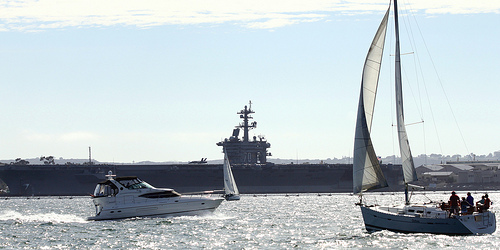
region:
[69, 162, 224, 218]
boat in the ocean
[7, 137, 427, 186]
large battleship in ocean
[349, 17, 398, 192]
sails being blown by wind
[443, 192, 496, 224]
people sitting on boat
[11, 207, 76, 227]
ripples caused by the boat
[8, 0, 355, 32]
clouds in the sky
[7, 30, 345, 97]
clear blue sky during the day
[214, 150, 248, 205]
small sailboat in the ocean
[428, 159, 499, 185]
houses in the background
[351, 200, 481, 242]
blue and white boat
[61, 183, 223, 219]
white boat on water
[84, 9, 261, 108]
blue and white sky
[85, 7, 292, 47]
thin clouds in sky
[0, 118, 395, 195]
large boat in distance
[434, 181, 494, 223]
people on small boat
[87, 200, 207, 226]
black stripe on boat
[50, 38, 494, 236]
boats on the water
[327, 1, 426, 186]
sail of the boat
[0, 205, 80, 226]
wave on the water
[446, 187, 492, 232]
people on the boat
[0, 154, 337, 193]
large boat on water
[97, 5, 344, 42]
the clouds are long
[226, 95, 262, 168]
top of the boat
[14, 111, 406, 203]
a big vessel on the water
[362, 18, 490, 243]
a sailboat on the water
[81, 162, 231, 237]
a motor boat on the water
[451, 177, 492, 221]
a group of people on the sailboat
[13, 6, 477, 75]
white clouds in a blue sky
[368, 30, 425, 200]
the sails of the sailboat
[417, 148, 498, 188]
buildings on the land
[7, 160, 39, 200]
the number seven on the side of the ship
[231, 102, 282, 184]
communication center of the ship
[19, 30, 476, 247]
four boats of different sizes on the water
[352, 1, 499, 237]
a larger sailboat with several people sailing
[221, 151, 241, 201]
a sail boat nearer to the ship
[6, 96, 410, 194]
a large commercial ship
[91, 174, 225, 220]
a large motorboat cruises by the sailboat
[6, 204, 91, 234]
wake left by the motor boat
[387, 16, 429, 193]
a rope ladder to top of mast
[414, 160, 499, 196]
buildings on the shore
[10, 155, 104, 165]
a hill behind the ship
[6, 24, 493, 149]
a light blue sky with a thin layer of clouds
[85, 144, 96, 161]
a crane on the ship's deck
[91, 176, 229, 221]
The white boat is speeding by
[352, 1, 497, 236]
The sailboat on the water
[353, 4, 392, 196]
The white sail on the boat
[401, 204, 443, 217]
The white cabin on the sailboat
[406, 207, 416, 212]
The window on the cabin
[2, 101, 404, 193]
The vessel in the water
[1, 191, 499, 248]
The water is rippling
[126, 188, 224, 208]
The railing on the white boat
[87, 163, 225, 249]
a boat out in the ocean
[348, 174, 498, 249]
a boat out in the ocean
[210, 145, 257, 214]
a boat out in the ocean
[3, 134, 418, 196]
a boat out in the ocean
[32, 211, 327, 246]
The blue ocean sea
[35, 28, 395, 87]
clear blue sky above the ocean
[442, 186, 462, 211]
a person on the small boat